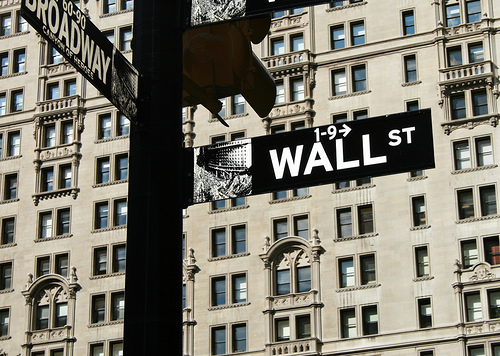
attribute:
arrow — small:
[339, 122, 359, 137]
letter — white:
[265, 141, 304, 179]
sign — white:
[255, 128, 426, 194]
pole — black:
[118, 5, 189, 354]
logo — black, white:
[192, 137, 254, 204]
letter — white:
[329, 137, 360, 174]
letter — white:
[279, 121, 408, 174]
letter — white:
[356, 132, 389, 165]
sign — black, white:
[179, 106, 436, 208]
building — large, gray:
[7, 107, 124, 344]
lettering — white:
[25, 0, 116, 85]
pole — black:
[118, 3, 202, 354]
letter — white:
[383, 124, 405, 148]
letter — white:
[401, 121, 417, 145]